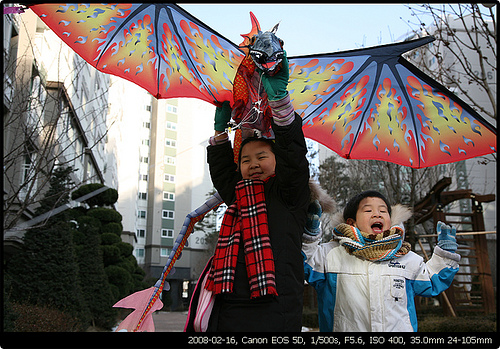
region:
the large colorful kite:
[2, 3, 499, 332]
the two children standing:
[182, 52, 458, 333]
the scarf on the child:
[328, 221, 410, 261]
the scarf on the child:
[203, 175, 278, 294]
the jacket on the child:
[305, 233, 460, 331]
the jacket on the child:
[206, 116, 308, 331]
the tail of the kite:
[111, 183, 220, 330]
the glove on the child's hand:
[307, 198, 322, 235]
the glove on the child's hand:
[436, 218, 456, 251]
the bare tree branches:
[5, 13, 122, 235]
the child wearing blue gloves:
[301, 188, 459, 329]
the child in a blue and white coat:
[302, 190, 457, 327]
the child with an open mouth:
[300, 187, 457, 327]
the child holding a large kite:
[202, 52, 307, 327]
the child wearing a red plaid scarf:
[202, 50, 307, 330]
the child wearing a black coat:
[202, 47, 307, 327]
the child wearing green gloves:
[205, 47, 310, 327]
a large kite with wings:
[25, 0, 495, 167]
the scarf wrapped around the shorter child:
[331, 221, 411, 261]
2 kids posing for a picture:
[160, 78, 478, 306]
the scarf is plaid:
[191, 169, 304, 319]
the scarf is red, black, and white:
[167, 165, 291, 322]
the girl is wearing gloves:
[158, 57, 321, 139]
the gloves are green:
[185, 57, 317, 142]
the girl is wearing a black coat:
[165, 105, 319, 325]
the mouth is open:
[352, 211, 392, 238]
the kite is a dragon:
[3, 1, 484, 183]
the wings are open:
[10, 0, 477, 157]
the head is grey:
[237, 27, 302, 88]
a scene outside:
[5, 3, 498, 330]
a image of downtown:
[4, 3, 494, 346]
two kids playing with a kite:
[44, 0, 491, 346]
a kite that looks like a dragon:
[18, 0, 498, 185]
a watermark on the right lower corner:
[183, 325, 498, 347]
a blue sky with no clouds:
[153, 0, 498, 90]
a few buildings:
[1, 0, 498, 260]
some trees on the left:
[0, 157, 152, 338]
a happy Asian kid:
[299, 182, 469, 342]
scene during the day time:
[2, 4, 496, 346]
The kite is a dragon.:
[16, 9, 498, 169]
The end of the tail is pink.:
[109, 287, 187, 334]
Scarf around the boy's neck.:
[340, 229, 421, 258]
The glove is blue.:
[423, 221, 463, 256]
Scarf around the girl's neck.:
[204, 189, 286, 309]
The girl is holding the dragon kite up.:
[236, 26, 298, 92]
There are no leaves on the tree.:
[398, 14, 499, 110]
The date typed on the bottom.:
[184, 334, 239, 348]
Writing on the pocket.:
[384, 275, 409, 298]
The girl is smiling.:
[232, 141, 278, 194]